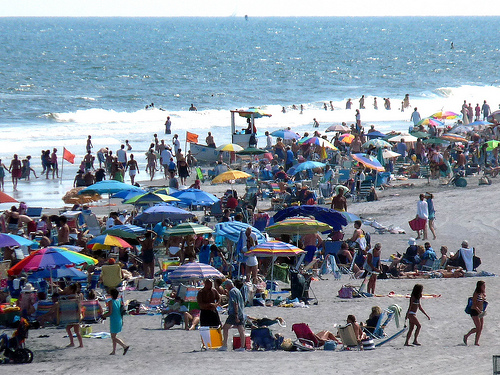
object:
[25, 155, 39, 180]
girl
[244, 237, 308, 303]
beach umbrella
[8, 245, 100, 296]
beach umbrella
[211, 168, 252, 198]
beach umbrella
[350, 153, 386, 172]
beach umbrella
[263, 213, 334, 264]
beach umbrella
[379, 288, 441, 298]
towel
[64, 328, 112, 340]
towel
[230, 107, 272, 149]
lifeguard tower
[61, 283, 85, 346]
person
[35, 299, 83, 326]
beach chair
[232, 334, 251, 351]
cooler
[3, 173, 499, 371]
sand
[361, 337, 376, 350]
bag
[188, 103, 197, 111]
people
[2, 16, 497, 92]
water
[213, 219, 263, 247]
umbrella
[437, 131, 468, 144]
umbrella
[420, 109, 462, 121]
umbrella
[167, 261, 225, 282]
umbrella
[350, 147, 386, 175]
umbrella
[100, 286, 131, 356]
woman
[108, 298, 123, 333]
dress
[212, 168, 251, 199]
umbrella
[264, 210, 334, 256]
umbrella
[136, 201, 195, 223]
umbrella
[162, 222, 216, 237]
umbrella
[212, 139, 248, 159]
umbrella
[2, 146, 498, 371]
beach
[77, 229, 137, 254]
umbrella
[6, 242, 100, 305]
umbrella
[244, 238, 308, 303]
umbrella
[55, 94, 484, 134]
wave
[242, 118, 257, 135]
life guard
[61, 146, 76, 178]
flag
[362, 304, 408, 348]
beach chair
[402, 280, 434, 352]
woman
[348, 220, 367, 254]
people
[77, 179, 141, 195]
umbrella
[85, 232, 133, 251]
umbrella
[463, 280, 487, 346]
girl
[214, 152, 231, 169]
people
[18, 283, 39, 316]
people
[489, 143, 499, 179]
people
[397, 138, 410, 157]
people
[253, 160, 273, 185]
people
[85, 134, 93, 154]
people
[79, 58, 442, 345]
scene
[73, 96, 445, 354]
scene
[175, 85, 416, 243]
scene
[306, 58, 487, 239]
scene